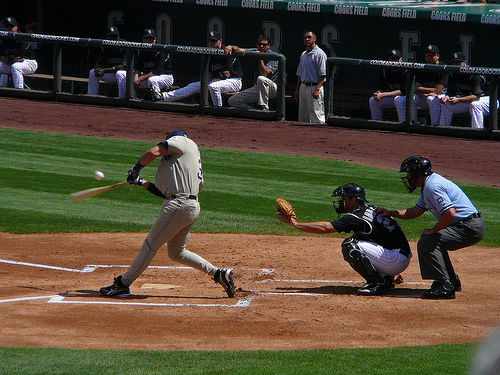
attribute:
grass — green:
[19, 138, 53, 166]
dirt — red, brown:
[66, 113, 102, 129]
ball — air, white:
[93, 168, 104, 181]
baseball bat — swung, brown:
[63, 182, 111, 198]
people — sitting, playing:
[129, 134, 450, 288]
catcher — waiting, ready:
[271, 181, 395, 287]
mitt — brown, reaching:
[272, 193, 298, 228]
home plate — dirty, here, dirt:
[149, 276, 231, 306]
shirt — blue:
[428, 181, 455, 206]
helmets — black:
[432, 44, 455, 57]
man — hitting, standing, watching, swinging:
[299, 36, 334, 122]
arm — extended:
[306, 216, 341, 235]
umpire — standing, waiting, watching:
[403, 161, 456, 289]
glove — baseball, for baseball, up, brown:
[122, 167, 137, 182]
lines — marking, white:
[40, 260, 65, 278]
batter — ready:
[128, 114, 228, 294]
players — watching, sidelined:
[136, 28, 257, 78]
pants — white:
[305, 100, 316, 114]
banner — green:
[406, 2, 428, 13]